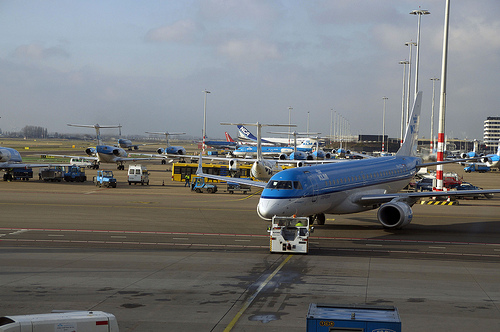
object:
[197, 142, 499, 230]
plane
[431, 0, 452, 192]
light pole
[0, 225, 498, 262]
runway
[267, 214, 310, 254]
vehicle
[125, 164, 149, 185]
van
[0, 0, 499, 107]
sky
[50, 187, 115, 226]
lines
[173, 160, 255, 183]
bus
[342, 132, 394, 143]
building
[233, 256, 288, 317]
oil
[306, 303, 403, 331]
container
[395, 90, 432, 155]
tail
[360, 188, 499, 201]
wings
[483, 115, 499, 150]
building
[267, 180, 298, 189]
windshield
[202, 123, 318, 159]
planes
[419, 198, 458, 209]
base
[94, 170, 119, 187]
car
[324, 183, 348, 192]
stripe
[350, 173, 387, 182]
windows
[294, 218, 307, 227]
people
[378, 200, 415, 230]
engines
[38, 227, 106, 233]
stripes